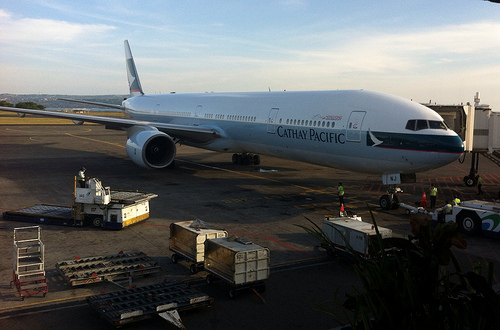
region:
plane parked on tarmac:
[42, 42, 459, 186]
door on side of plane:
[333, 98, 371, 149]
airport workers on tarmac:
[329, 178, 456, 210]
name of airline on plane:
[270, 123, 352, 150]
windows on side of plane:
[207, 106, 258, 131]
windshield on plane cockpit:
[396, 111, 456, 141]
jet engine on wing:
[127, 122, 186, 177]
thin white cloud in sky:
[333, 24, 440, 74]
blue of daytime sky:
[285, 3, 365, 31]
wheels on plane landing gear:
[373, 173, 408, 216]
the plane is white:
[51, 40, 491, 300]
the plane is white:
[97, 63, 407, 228]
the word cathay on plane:
[273, 123, 308, 144]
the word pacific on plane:
[306, 126, 348, 147]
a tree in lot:
[298, 209, 498, 326]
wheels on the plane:
[229, 148, 264, 173]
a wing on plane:
[0, 101, 230, 136]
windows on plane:
[201, 112, 338, 129]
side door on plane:
[264, 103, 283, 137]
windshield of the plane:
[398, 116, 452, 133]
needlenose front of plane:
[411, 123, 468, 168]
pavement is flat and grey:
[6, 128, 68, 163]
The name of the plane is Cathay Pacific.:
[65, 38, 467, 188]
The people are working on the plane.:
[330, 169, 469, 217]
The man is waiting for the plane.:
[60, 159, 104, 196]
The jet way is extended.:
[442, 105, 498, 143]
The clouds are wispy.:
[13, 15, 434, 77]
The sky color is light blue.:
[137, 5, 304, 37]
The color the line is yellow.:
[58, 126, 133, 161]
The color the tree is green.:
[5, 97, 50, 120]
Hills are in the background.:
[5, 74, 142, 105]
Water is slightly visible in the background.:
[41, 105, 124, 113]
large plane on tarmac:
[106, 10, 445, 265]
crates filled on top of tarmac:
[114, 184, 281, 314]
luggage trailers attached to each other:
[54, 205, 314, 322]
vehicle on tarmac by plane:
[77, 160, 147, 248]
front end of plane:
[382, 104, 459, 175]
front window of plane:
[357, 114, 444, 151]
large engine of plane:
[50, 125, 192, 187]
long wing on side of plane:
[0, 81, 191, 143]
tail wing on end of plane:
[121, 24, 165, 106]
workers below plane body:
[334, 192, 479, 256]